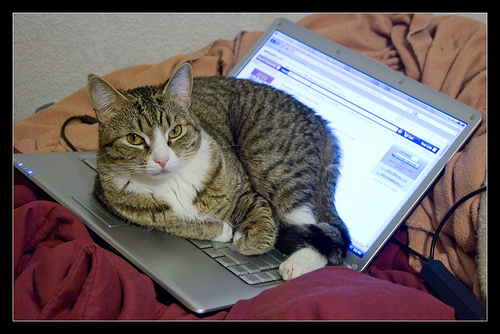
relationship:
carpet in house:
[19, 19, 233, 87] [13, 13, 493, 322]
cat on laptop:
[80, 59, 353, 269] [63, 36, 473, 310]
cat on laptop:
[88, 63, 353, 283] [15, 13, 481, 313]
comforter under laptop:
[13, 148, 453, 318] [15, 13, 481, 313]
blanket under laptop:
[13, 13, 487, 297] [15, 13, 481, 313]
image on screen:
[237, 36, 466, 249] [181, 28, 463, 258]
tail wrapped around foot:
[271, 214, 353, 257] [275, 235, 333, 286]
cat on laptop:
[80, 59, 353, 269] [15, 13, 481, 313]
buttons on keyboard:
[208, 239, 274, 275] [23, 12, 453, 317]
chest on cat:
[108, 133, 228, 223] [73, 55, 313, 239]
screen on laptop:
[228, 25, 465, 276] [15, 13, 481, 313]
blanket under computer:
[17, 20, 474, 329] [16, 32, 446, 302]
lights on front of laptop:
[10, 155, 34, 179] [15, 13, 481, 313]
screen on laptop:
[233, 28, 467, 258] [15, 13, 481, 313]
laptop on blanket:
[15, 13, 481, 313] [12, 12, 478, 282]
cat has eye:
[80, 59, 353, 269] [121, 125, 151, 151]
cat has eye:
[80, 59, 353, 269] [164, 119, 190, 142]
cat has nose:
[80, 59, 353, 269] [153, 148, 172, 167]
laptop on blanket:
[13, 18, 481, 312] [12, 12, 478, 282]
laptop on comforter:
[13, 18, 481, 312] [13, 148, 454, 320]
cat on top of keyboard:
[80, 59, 353, 269] [81, 148, 336, 288]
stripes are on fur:
[264, 160, 281, 172] [109, 88, 327, 223]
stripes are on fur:
[240, 194, 257, 218] [109, 88, 327, 223]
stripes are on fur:
[110, 202, 169, 215] [109, 88, 327, 223]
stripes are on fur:
[193, 157, 223, 201] [109, 88, 327, 223]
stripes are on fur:
[257, 91, 268, 108] [109, 88, 327, 223]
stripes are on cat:
[264, 160, 281, 172] [80, 59, 353, 269]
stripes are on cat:
[240, 194, 257, 218] [80, 59, 353, 269]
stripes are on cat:
[110, 202, 169, 215] [80, 59, 353, 269]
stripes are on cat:
[193, 157, 223, 201] [80, 59, 353, 269]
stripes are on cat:
[257, 91, 268, 108] [80, 59, 353, 269]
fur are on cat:
[109, 88, 327, 223] [80, 59, 353, 269]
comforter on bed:
[13, 148, 454, 320] [12, 8, 480, 317]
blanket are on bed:
[13, 13, 487, 297] [12, 8, 480, 317]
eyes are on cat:
[119, 122, 181, 145] [80, 59, 353, 269]